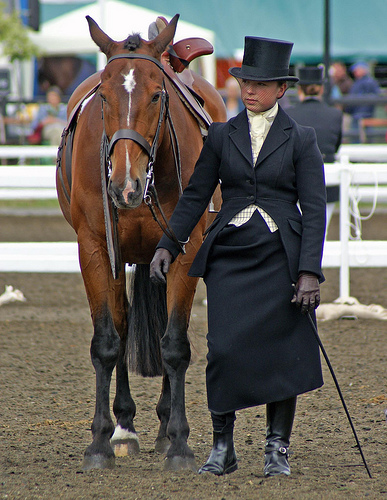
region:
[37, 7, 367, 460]
a woman with a beautiful horse.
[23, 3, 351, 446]
well dressed woman with a beautiful horse.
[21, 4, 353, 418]
a lady with an attractive horse.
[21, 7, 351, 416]
a nicely dressed lady with an attractive horse.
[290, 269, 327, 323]
dark glove worn on hand.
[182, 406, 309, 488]
black boots in dirt.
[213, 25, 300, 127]
person wearing a large hat.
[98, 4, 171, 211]
head of a horse.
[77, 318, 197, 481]
legs of a horse.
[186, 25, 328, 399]
person dressed in black outfit.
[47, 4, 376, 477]
Woman and horse walking along competition course.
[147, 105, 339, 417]
Woman dressed in riding habit.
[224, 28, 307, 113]
Woman wearing black top hat with veil.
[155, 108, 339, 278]
Woman dressed in tailored black riding jacket.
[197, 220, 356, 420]
Woman dressed in long black riding skirt.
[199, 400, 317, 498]
Woman wearing black leather riding boots.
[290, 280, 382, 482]
Woman carrying black riding crop.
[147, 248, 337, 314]
Woman wearing brown leather gloves.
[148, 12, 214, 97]
Horse mounted with English side saddle.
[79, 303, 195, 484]
Two front black legs of horse.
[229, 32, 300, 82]
woman with black hat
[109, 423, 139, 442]
white spot on horse's foot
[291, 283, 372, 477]
woman holding black whip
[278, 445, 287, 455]
silver buckle on black boot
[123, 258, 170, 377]
long black tail between legs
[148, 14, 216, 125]
red saddle on horse's back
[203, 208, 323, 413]
woman wearing black skirt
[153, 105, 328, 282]
woman wearing black jacket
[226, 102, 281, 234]
woman wearing white shirt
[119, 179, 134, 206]
pink patch on horse's nose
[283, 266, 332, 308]
brown glove on woman's hand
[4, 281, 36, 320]
small white spot on the dirt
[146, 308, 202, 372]
horse's black knees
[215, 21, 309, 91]
large top hat on woman's head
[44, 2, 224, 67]
triangle top of white building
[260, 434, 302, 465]
white buckle on black boots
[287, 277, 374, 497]
black riding crop in woman's hand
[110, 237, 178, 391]
large manicured tail on horse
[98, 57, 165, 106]
white spot on brown horse's face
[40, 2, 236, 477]
Horse is brown and black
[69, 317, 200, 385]
Knees of horse are black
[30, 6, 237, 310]
Body of horse is brown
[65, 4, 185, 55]
Brown pointy ears of horse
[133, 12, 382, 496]
Person wearing a suit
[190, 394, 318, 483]
Boots are black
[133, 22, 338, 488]
Person wears a hat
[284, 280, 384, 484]
Whip hold in left hand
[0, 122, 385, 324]
Fence is white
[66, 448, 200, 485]
Hooves of horse are black